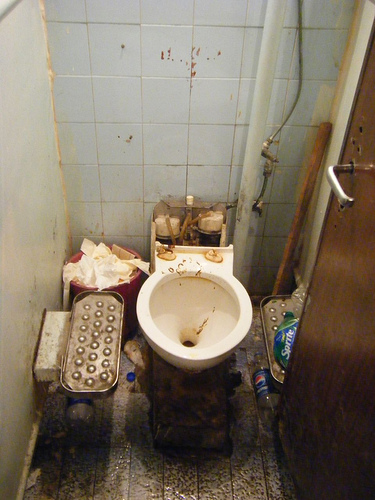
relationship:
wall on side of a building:
[90, 21, 165, 109] [1, 2, 358, 494]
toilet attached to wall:
[133, 208, 253, 370] [37, 4, 356, 300]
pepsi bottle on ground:
[252, 346, 280, 429] [22, 301, 302, 498]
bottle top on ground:
[127, 371, 134, 381] [22, 301, 302, 498]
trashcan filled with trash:
[70, 244, 140, 338] [62, 237, 148, 305]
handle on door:
[325, 162, 354, 207] [297, 20, 372, 498]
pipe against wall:
[230, 1, 289, 285] [37, 4, 356, 300]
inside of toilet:
[152, 203, 221, 245] [138, 200, 252, 424]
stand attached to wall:
[33, 290, 127, 396] [2, 4, 71, 485]